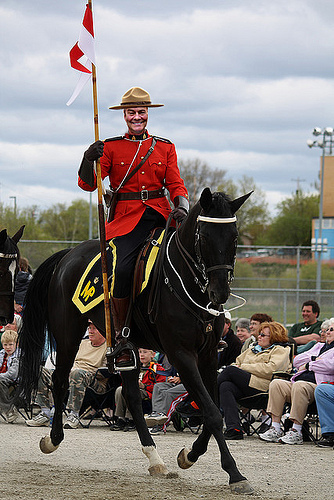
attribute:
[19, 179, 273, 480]
horse — black, ridden, dark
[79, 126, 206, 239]
jacket — red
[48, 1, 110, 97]
flag — carried, white, red, held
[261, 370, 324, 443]
slacks — tan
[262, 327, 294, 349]
sunglasses — dark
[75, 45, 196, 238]
man — smiling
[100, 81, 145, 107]
hat — here, worn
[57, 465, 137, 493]
rocks — grey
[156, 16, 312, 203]
sky — overcast, blue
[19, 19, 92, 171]
cloud — grey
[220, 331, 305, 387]
jacket — tan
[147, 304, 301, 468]
woman — sitting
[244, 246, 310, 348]
fence — here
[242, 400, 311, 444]
shoes — white]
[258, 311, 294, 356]
hair — red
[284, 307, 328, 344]
shirt — green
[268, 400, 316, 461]
sneakers — white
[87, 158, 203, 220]
coat — red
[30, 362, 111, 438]
pants — camoflauge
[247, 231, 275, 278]
car — here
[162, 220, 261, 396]
bridle — white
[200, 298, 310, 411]
people — watching, sitting